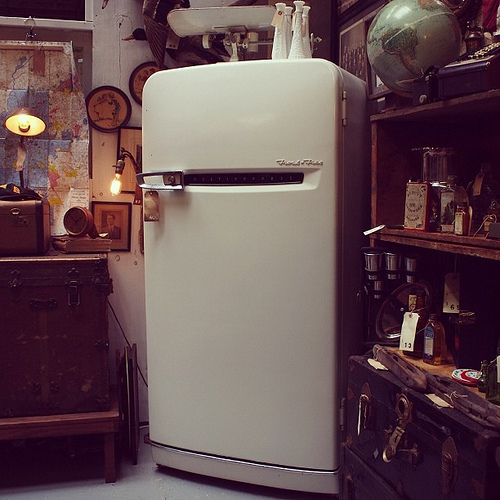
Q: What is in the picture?
A: Fridge.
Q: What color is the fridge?
A: White.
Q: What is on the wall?
A: Drawings.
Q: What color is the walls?
A: Porcelain.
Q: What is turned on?
A: Lights.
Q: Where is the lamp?
A: On the shelf.